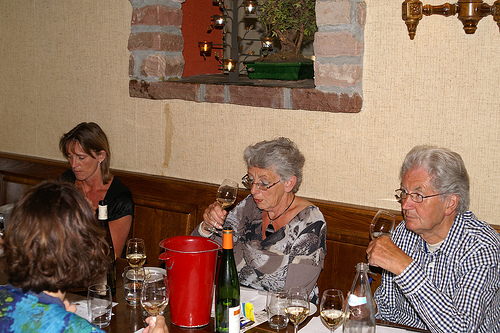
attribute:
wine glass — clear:
[217, 179, 237, 208]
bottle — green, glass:
[220, 223, 239, 332]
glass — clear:
[91, 285, 112, 326]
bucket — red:
[161, 236, 218, 327]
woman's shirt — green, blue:
[1, 292, 105, 332]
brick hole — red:
[135, 5, 355, 111]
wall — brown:
[2, 3, 499, 213]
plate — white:
[127, 267, 167, 282]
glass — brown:
[125, 237, 148, 287]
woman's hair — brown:
[61, 130, 112, 157]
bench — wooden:
[3, 162, 494, 308]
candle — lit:
[199, 43, 213, 53]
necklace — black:
[265, 212, 277, 236]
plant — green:
[251, 4, 312, 79]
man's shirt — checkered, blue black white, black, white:
[390, 219, 498, 329]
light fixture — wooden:
[400, 2, 498, 44]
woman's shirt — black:
[56, 172, 140, 233]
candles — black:
[199, 2, 275, 69]